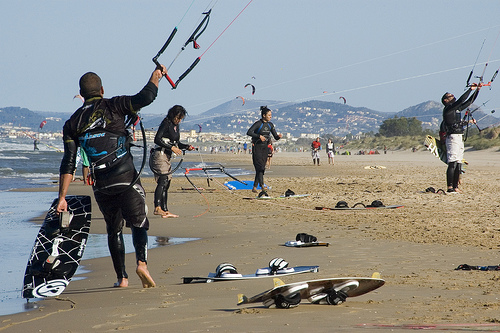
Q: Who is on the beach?
A: People holding strings.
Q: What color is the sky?
A: Blue.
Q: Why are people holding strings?
A: To fly kites.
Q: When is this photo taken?
A: Daytime.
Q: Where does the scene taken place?
A: On a beach.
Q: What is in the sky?
A: Kites.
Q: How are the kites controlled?
A: Through strings.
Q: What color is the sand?
A: Tan.